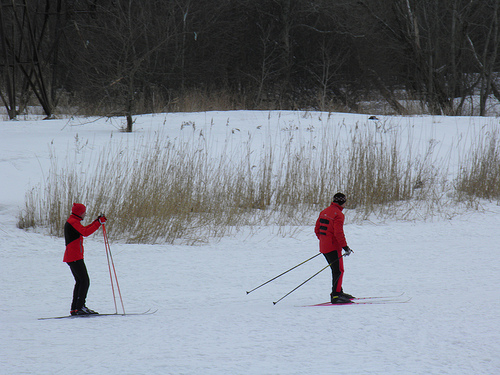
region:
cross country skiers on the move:
[36, 184, 418, 325]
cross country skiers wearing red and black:
[44, 179, 409, 325]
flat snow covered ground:
[61, 320, 470, 363]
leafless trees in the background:
[3, 12, 490, 107]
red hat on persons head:
[57, 197, 93, 222]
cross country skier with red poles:
[37, 197, 142, 322]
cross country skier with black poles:
[236, 185, 385, 317]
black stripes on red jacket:
[307, 207, 352, 253]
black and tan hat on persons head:
[326, 189, 349, 207]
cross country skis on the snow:
[28, 285, 431, 331]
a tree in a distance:
[8, 10, 53, 123]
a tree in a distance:
[74, 17, 161, 149]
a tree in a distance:
[167, 20, 208, 131]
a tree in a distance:
[113, 50, 142, 140]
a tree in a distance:
[178, 7, 221, 105]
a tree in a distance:
[224, 15, 249, 106]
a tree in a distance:
[333, 32, 403, 127]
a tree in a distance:
[475, 21, 499, 116]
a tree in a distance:
[406, 16, 454, 135]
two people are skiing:
[19, 138, 458, 345]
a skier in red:
[32, 162, 180, 371]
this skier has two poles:
[218, 156, 413, 366]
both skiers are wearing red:
[11, 131, 461, 345]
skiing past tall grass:
[8, 100, 392, 357]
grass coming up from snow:
[131, 101, 253, 261]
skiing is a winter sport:
[16, 84, 478, 358]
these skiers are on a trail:
[8, 130, 442, 349]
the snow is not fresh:
[31, 169, 422, 351]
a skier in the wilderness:
[11, 59, 171, 343]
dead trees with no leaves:
[8, 5, 495, 112]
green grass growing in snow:
[110, 149, 300, 252]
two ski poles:
[96, 232, 141, 312]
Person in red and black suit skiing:
[41, 196, 182, 343]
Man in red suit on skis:
[225, 178, 435, 353]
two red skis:
[304, 290, 442, 319]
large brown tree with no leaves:
[100, 0, 143, 135]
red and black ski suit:
[56, 217, 90, 259]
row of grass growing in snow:
[109, 112, 318, 251]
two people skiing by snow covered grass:
[12, 168, 498, 373]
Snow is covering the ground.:
[16, 106, 473, 366]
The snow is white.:
[167, 267, 280, 354]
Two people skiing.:
[50, 179, 412, 326]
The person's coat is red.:
[65, 190, 126, 277]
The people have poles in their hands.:
[83, 190, 330, 322]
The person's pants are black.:
[50, 201, 114, 351]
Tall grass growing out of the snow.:
[54, 137, 428, 217]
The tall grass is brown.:
[58, 141, 277, 218]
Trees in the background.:
[24, 15, 460, 106]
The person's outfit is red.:
[294, 164, 369, 306]